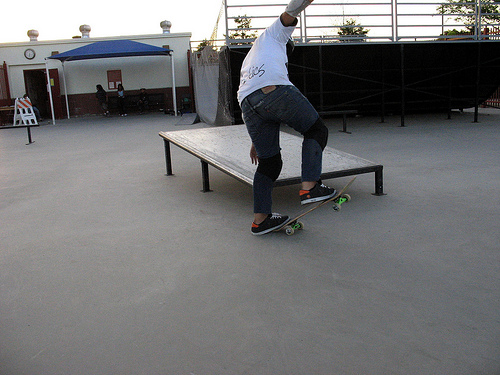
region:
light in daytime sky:
[1, 1, 466, 43]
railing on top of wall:
[206, 0, 498, 52]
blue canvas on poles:
[47, 40, 176, 125]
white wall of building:
[7, 31, 192, 99]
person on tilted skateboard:
[239, 1, 354, 236]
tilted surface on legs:
[160, 124, 385, 204]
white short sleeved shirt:
[236, 15, 299, 106]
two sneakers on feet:
[253, 184, 336, 233]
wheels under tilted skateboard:
[285, 191, 352, 235]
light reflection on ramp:
[165, 119, 248, 175]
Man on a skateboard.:
[230, 5, 366, 244]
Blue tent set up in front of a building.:
[43, 35, 185, 120]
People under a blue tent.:
[87, 78, 160, 123]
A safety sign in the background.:
[10, 91, 37, 132]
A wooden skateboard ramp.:
[158, 115, 393, 225]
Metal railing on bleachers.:
[219, 5, 499, 54]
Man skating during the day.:
[0, 0, 497, 371]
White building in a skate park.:
[2, 33, 204, 116]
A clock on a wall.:
[17, 45, 42, 62]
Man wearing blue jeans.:
[222, 2, 364, 243]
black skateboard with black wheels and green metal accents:
[267, 171, 362, 241]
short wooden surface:
[146, 103, 402, 216]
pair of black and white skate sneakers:
[243, 178, 346, 238]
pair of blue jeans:
[222, 85, 335, 218]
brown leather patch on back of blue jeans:
[256, 81, 288, 96]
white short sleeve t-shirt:
[225, 13, 308, 108]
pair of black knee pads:
[251, 116, 336, 183]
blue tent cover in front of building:
[44, 33, 179, 65]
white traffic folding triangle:
[8, 90, 43, 130]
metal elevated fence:
[187, 0, 499, 50]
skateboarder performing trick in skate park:
[238, 0, 351, 237]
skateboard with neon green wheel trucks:
[275, 177, 355, 235]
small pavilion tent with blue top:
[44, 39, 177, 122]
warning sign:
[12, 97, 37, 126]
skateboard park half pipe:
[188, 0, 498, 135]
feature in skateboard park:
[158, 123, 385, 199]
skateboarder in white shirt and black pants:
[237, 1, 352, 240]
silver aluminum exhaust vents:
[25, 20, 171, 40]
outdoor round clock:
[23, 49, 35, 59]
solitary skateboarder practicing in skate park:
[0, 0, 495, 371]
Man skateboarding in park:
[210, 5, 393, 285]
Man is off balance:
[216, 10, 401, 274]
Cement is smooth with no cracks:
[94, 205, 231, 361]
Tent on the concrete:
[34, 22, 202, 142]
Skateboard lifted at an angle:
[237, 173, 373, 265]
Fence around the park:
[331, 0, 471, 49]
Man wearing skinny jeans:
[226, 84, 333, 214]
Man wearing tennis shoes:
[230, 195, 312, 272]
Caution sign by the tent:
[6, 86, 48, 140]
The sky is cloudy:
[130, 1, 174, 43]